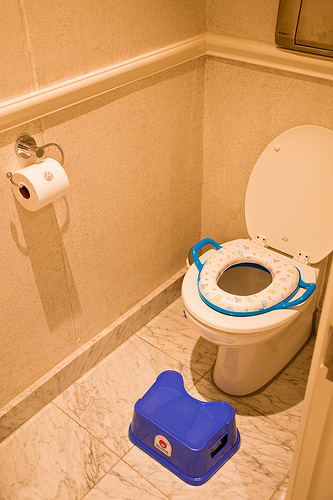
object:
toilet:
[179, 122, 333, 398]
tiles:
[2, 265, 331, 497]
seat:
[190, 234, 319, 316]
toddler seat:
[186, 234, 317, 317]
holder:
[274, 0, 332, 63]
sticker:
[146, 428, 181, 460]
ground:
[0, 366, 293, 499]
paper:
[12, 156, 71, 213]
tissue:
[9, 158, 70, 212]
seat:
[181, 237, 321, 336]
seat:
[246, 121, 333, 254]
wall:
[0, 0, 206, 443]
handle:
[205, 433, 234, 452]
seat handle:
[192, 237, 221, 272]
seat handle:
[273, 278, 315, 308]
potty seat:
[191, 237, 316, 315]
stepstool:
[128, 370, 240, 488]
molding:
[0, 34, 208, 148]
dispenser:
[5, 131, 65, 192]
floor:
[0, 300, 318, 498]